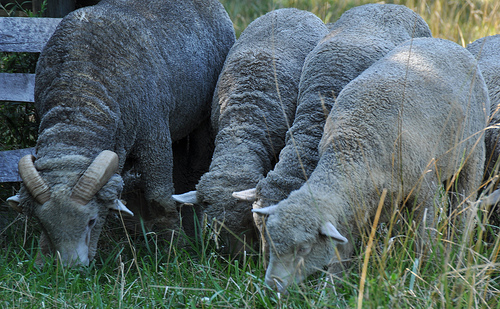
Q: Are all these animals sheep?
A: No, there are both sheep and goats.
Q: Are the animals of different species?
A: Yes, they are sheep and goats.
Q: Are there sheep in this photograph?
A: Yes, there is a sheep.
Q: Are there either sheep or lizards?
A: Yes, there is a sheep.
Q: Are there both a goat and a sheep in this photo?
A: Yes, there are both a sheep and a goat.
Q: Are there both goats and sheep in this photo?
A: Yes, there are both a sheep and a goat.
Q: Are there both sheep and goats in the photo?
A: Yes, there are both a sheep and a goat.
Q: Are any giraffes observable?
A: No, there are no giraffes.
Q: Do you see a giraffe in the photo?
A: No, there are no giraffes.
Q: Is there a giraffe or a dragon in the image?
A: No, there are no giraffes or dragons.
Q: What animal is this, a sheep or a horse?
A: This is a sheep.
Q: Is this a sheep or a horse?
A: This is a sheep.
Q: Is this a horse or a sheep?
A: This is a sheep.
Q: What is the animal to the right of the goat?
A: The animal is a sheep.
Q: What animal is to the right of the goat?
A: The animal is a sheep.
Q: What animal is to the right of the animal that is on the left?
A: The animal is a sheep.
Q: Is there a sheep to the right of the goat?
A: Yes, there is a sheep to the right of the goat.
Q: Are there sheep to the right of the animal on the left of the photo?
A: Yes, there is a sheep to the right of the goat.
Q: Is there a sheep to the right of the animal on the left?
A: Yes, there is a sheep to the right of the goat.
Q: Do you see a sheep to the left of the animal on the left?
A: No, the sheep is to the right of the goat.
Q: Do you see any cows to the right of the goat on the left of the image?
A: No, there is a sheep to the right of the goat.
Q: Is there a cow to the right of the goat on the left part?
A: No, there is a sheep to the right of the goat.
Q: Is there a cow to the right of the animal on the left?
A: No, there is a sheep to the right of the goat.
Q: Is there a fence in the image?
A: Yes, there is a fence.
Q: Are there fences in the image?
A: Yes, there is a fence.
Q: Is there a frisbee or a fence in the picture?
A: Yes, there is a fence.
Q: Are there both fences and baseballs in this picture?
A: No, there is a fence but no baseballs.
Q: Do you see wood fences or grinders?
A: Yes, there is a wood fence.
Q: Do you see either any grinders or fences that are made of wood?
A: Yes, the fence is made of wood.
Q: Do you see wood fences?
A: Yes, there is a fence that is made of wood.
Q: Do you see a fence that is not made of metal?
A: Yes, there is a fence that is made of wood.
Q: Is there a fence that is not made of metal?
A: Yes, there is a fence that is made of wood.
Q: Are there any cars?
A: No, there are no cars.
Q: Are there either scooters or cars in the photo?
A: No, there are no cars or scooters.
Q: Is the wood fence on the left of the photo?
A: Yes, the fence is on the left of the image.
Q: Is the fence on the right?
A: No, the fence is on the left of the image.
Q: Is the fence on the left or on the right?
A: The fence is on the left of the image.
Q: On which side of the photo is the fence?
A: The fence is on the left of the image.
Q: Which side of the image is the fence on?
A: The fence is on the left of the image.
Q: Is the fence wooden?
A: Yes, the fence is wooden.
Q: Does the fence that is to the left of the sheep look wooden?
A: Yes, the fence is wooden.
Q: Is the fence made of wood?
A: Yes, the fence is made of wood.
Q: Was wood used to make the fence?
A: Yes, the fence is made of wood.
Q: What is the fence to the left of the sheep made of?
A: The fence is made of wood.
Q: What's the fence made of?
A: The fence is made of wood.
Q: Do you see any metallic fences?
A: No, there is a fence but it is wooden.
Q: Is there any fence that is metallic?
A: No, there is a fence but it is wooden.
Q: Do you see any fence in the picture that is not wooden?
A: No, there is a fence but it is wooden.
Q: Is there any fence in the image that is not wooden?
A: No, there is a fence but it is wooden.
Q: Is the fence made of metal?
A: No, the fence is made of wood.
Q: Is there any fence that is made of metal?
A: No, there is a fence but it is made of wood.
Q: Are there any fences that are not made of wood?
A: No, there is a fence but it is made of wood.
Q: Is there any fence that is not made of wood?
A: No, there is a fence but it is made of wood.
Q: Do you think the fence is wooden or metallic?
A: The fence is wooden.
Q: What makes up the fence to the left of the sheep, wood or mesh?
A: The fence is made of wood.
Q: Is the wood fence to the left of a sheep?
A: Yes, the fence is to the left of a sheep.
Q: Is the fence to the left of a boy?
A: No, the fence is to the left of a sheep.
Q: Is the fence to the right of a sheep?
A: No, the fence is to the left of a sheep.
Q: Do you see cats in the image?
A: No, there are no cats.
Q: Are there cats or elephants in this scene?
A: No, there are no cats or elephants.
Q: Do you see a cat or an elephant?
A: No, there are no cats or elephants.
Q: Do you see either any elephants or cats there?
A: No, there are no cats or elephants.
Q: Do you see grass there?
A: Yes, there is grass.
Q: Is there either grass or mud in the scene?
A: Yes, there is grass.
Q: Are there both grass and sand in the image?
A: No, there is grass but no sand.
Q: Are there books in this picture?
A: No, there are no books.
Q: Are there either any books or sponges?
A: No, there are no books or sponges.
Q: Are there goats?
A: Yes, there is a goat.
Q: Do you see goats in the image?
A: Yes, there is a goat.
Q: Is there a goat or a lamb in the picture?
A: Yes, there is a goat.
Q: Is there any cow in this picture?
A: No, there are no cows.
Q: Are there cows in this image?
A: No, there are no cows.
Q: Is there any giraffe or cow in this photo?
A: No, there are no cows or giraffes.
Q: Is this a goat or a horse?
A: This is a goat.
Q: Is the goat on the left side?
A: Yes, the goat is on the left of the image.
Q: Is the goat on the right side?
A: No, the goat is on the left of the image.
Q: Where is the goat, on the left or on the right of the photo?
A: The goat is on the left of the image.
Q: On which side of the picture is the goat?
A: The goat is on the left of the image.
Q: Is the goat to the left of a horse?
A: No, the goat is to the left of a sheep.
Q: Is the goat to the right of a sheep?
A: No, the goat is to the left of a sheep.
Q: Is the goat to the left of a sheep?
A: Yes, the goat is to the left of a sheep.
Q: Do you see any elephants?
A: No, there are no elephants.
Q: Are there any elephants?
A: No, there are no elephants.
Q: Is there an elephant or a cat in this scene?
A: No, there are no elephants or cats.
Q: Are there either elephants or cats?
A: No, there are no elephants or cats.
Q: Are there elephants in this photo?
A: No, there are no elephants.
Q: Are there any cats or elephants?
A: No, there are no elephants or cats.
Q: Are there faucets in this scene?
A: No, there are no faucets.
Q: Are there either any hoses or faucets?
A: No, there are no faucets or hoses.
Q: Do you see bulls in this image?
A: No, there are no bulls.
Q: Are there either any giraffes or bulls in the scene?
A: No, there are no bulls or giraffes.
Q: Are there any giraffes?
A: No, there are no giraffes.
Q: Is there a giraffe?
A: No, there are no giraffes.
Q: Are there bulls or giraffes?
A: No, there are no giraffes or bulls.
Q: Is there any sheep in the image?
A: Yes, there is a sheep.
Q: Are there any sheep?
A: Yes, there is a sheep.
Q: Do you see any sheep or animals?
A: Yes, there is a sheep.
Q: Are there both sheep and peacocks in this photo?
A: No, there is a sheep but no peacocks.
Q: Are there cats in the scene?
A: No, there are no cats.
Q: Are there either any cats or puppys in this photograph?
A: No, there are no cats or puppys.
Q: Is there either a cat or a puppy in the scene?
A: No, there are no cats or puppys.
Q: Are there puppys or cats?
A: No, there are no cats or puppys.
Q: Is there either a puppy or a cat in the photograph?
A: No, there are no cats or puppys.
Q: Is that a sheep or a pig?
A: That is a sheep.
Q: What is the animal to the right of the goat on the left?
A: The animal is a sheep.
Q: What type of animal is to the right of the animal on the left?
A: The animal is a sheep.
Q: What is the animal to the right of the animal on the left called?
A: The animal is a sheep.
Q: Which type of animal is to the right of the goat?
A: The animal is a sheep.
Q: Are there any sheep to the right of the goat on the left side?
A: Yes, there is a sheep to the right of the goat.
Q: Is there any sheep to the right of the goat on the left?
A: Yes, there is a sheep to the right of the goat.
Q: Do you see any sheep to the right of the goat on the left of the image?
A: Yes, there is a sheep to the right of the goat.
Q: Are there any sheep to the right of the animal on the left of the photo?
A: Yes, there is a sheep to the right of the goat.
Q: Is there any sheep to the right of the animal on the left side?
A: Yes, there is a sheep to the right of the goat.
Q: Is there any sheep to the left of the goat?
A: No, the sheep is to the right of the goat.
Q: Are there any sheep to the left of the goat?
A: No, the sheep is to the right of the goat.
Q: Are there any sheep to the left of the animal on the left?
A: No, the sheep is to the right of the goat.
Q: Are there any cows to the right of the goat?
A: No, there is a sheep to the right of the goat.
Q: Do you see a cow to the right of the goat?
A: No, there is a sheep to the right of the goat.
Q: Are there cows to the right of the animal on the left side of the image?
A: No, there is a sheep to the right of the goat.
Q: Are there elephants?
A: No, there are no elephants.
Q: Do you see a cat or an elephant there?
A: No, there are no elephants or cats.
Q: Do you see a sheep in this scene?
A: Yes, there is a sheep.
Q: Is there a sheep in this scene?
A: Yes, there is a sheep.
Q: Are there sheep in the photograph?
A: Yes, there is a sheep.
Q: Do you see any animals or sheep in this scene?
A: Yes, there is a sheep.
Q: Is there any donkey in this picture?
A: No, there are no donkeys.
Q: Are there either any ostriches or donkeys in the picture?
A: No, there are no donkeys or ostriches.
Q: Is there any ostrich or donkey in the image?
A: No, there are no donkeys or ostriches.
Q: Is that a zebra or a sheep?
A: That is a sheep.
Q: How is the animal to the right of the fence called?
A: The animal is a sheep.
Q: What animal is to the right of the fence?
A: The animal is a sheep.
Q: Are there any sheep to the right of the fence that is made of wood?
A: Yes, there is a sheep to the right of the fence.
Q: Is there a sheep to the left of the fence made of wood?
A: No, the sheep is to the right of the fence.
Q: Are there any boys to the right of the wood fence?
A: No, there is a sheep to the right of the fence.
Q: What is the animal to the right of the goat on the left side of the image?
A: The animal is a sheep.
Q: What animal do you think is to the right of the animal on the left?
A: The animal is a sheep.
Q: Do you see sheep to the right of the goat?
A: Yes, there is a sheep to the right of the goat.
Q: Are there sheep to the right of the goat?
A: Yes, there is a sheep to the right of the goat.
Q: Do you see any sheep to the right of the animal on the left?
A: Yes, there is a sheep to the right of the goat.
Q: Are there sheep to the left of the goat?
A: No, the sheep is to the right of the goat.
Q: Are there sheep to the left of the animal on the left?
A: No, the sheep is to the right of the goat.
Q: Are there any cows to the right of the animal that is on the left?
A: No, there is a sheep to the right of the goat.